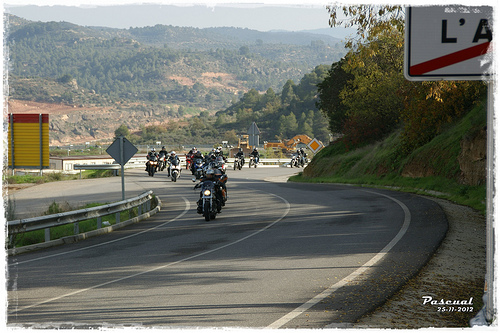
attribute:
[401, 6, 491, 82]
sign — white 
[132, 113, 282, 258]
motorcycles — many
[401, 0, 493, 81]
street sign — white 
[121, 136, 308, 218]
crew — riding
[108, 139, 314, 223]
pack — riding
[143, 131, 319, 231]
motorcyclists — riding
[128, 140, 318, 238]
motorcyclists — heading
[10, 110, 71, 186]
sign — large, red, yellow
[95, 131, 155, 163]
sign — diamond shaped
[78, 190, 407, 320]
lines — white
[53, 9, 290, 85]
hills — rolling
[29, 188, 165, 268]
barrier — center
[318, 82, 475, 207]
bank — grassy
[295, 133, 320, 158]
sign — yellow, white, diamond